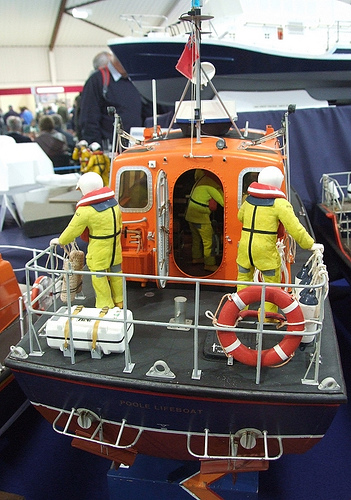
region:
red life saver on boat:
[207, 284, 303, 377]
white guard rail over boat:
[27, 269, 331, 339]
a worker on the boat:
[50, 168, 130, 315]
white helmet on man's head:
[256, 169, 284, 186]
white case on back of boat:
[41, 302, 137, 357]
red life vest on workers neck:
[78, 187, 118, 203]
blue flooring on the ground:
[308, 450, 348, 496]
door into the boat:
[141, 171, 171, 275]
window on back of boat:
[119, 167, 147, 209]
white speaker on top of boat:
[192, 51, 214, 97]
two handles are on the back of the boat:
[45, 411, 331, 489]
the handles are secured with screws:
[67, 400, 301, 498]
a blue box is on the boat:
[94, 450, 260, 494]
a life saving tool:
[222, 285, 334, 395]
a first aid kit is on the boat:
[37, 295, 162, 371]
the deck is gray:
[151, 324, 217, 370]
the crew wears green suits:
[82, 203, 233, 361]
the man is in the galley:
[167, 165, 287, 249]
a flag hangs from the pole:
[147, 38, 270, 117]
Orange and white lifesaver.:
[205, 283, 306, 370]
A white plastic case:
[45, 304, 136, 352]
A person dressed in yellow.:
[235, 166, 323, 292]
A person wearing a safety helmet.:
[47, 167, 124, 273]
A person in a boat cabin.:
[184, 172, 224, 273]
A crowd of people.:
[1, 99, 81, 165]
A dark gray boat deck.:
[0, 264, 347, 402]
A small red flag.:
[175, 31, 200, 80]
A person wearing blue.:
[78, 51, 142, 146]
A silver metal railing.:
[25, 245, 324, 384]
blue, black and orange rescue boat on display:
[3, 2, 346, 475]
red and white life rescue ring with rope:
[215, 285, 302, 370]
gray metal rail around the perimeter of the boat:
[18, 197, 328, 381]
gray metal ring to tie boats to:
[146, 360, 178, 385]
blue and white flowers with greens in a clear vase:
[8, 343, 30, 367]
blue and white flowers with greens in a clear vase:
[321, 377, 342, 400]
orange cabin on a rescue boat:
[110, 136, 286, 299]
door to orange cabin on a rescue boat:
[148, 168, 226, 286]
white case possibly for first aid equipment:
[39, 305, 134, 358]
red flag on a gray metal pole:
[170, 29, 202, 92]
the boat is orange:
[83, 118, 314, 218]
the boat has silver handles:
[48, 391, 343, 494]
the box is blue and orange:
[100, 455, 332, 491]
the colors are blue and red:
[49, 390, 256, 496]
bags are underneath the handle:
[56, 418, 162, 468]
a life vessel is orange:
[223, 281, 335, 402]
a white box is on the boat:
[42, 303, 245, 398]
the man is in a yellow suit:
[231, 198, 328, 306]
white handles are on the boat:
[129, 339, 204, 408]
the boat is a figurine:
[46, 110, 322, 336]